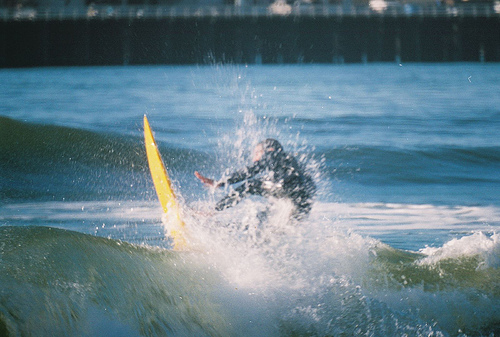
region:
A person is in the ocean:
[13, 42, 494, 328]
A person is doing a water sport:
[30, 35, 463, 320]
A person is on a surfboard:
[51, 52, 491, 312]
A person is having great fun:
[46, 62, 442, 318]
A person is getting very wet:
[35, 58, 440, 306]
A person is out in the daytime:
[11, 60, 496, 308]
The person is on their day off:
[40, 57, 427, 302]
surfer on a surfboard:
[140, 116, 316, 263]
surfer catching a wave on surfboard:
[142, 116, 315, 256]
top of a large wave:
[3, 223, 495, 332]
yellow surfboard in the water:
[143, 110, 191, 251]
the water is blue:
[2, 63, 494, 333]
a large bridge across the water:
[5, 13, 497, 65]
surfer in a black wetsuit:
[196, 138, 317, 218]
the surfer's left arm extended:
[196, 155, 273, 182]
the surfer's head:
[253, 139, 279, 159]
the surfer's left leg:
[211, 179, 294, 213]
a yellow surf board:
[116, 95, 231, 270]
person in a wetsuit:
[216, 123, 348, 263]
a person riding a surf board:
[120, 90, 386, 305]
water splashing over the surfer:
[198, 93, 335, 249]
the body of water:
[19, 38, 489, 331]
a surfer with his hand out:
[178, 83, 340, 264]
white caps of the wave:
[426, 206, 495, 305]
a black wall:
[6, 15, 498, 87]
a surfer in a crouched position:
[168, 102, 348, 260]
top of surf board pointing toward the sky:
[108, 88, 237, 260]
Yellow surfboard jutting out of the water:
[139, 113, 212, 265]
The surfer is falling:
[193, 138, 322, 238]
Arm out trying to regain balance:
[188, 151, 273, 189]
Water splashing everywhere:
[55, 66, 445, 333]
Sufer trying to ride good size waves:
[3, 106, 498, 335]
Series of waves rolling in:
[4, 106, 495, 335]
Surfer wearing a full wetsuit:
[194, 138, 319, 225]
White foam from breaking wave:
[93, 223, 499, 266]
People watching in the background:
[3, 1, 498, 16]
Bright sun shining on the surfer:
[108, 53, 495, 305]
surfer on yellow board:
[107, 102, 314, 264]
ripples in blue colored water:
[312, 63, 372, 117]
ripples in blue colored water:
[8, 201, 83, 251]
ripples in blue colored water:
[38, 99, 79, 154]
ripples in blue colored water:
[171, 91, 199, 111]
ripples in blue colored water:
[55, 82, 96, 133]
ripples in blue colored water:
[350, 132, 410, 177]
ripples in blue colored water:
[404, 168, 438, 216]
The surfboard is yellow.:
[135, 103, 196, 255]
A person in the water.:
[189, 139, 354, 239]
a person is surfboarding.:
[189, 144, 338, 250]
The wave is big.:
[7, 100, 194, 320]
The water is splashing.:
[203, 198, 366, 278]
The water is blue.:
[66, 63, 491, 138]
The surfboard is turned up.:
[131, 119, 206, 247]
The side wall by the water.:
[95, 17, 464, 75]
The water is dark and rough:
[108, 54, 480, 122]